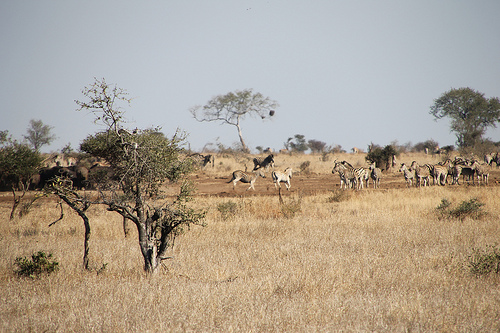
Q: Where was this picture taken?
A: Africa.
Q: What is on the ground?
A: Brown brush.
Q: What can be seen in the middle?
A: Herd of animals.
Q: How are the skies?
A: Grey and clear.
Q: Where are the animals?
A: In the plains.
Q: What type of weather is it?
A: Hot.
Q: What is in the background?
A: Trees.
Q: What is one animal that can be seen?
A: Lion.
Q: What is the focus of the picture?
A: The animals.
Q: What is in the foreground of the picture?
A: A dead tree.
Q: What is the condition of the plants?
A: Dead.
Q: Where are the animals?
A: Grassy field.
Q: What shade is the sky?
A: Gray.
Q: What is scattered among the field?
A: Trees.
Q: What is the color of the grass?
A: Brown.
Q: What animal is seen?
A: Zebra, elephant.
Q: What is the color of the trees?
A: Green.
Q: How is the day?
A: Sunny.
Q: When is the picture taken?
A: Daytime.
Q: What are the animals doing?
A: Walking.